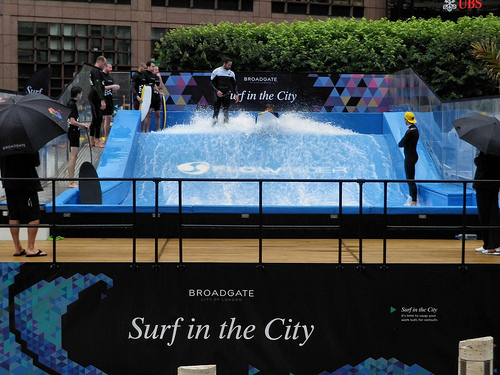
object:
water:
[119, 107, 409, 207]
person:
[397, 111, 420, 206]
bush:
[416, 11, 500, 103]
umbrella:
[0, 92, 75, 155]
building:
[0, 0, 389, 99]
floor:
[0, 236, 499, 265]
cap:
[404, 111, 418, 124]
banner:
[0, 260, 500, 375]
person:
[208, 56, 240, 127]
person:
[87, 55, 108, 149]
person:
[65, 86, 89, 188]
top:
[397, 124, 420, 155]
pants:
[403, 153, 418, 201]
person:
[131, 62, 155, 133]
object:
[138, 84, 152, 123]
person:
[0, 93, 73, 257]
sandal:
[25, 248, 47, 257]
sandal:
[12, 248, 26, 256]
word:
[188, 288, 255, 298]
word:
[128, 316, 185, 346]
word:
[186, 317, 211, 340]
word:
[218, 316, 256, 340]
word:
[264, 317, 315, 346]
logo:
[175, 161, 349, 175]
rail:
[0, 176, 499, 274]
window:
[17, 21, 36, 35]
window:
[115, 24, 133, 38]